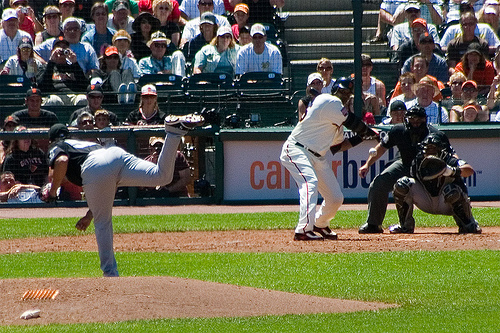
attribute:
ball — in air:
[367, 145, 378, 161]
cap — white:
[238, 20, 293, 44]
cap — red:
[138, 78, 156, 98]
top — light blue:
[203, 39, 248, 81]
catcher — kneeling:
[381, 134, 482, 250]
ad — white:
[221, 136, 498, 201]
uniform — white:
[251, 89, 355, 244]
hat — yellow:
[410, 74, 437, 97]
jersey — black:
[40, 113, 90, 189]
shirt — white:
[269, 87, 356, 171]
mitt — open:
[404, 156, 456, 194]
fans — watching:
[9, 1, 498, 122]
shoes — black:
[292, 226, 341, 244]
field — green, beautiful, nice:
[356, 244, 499, 320]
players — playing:
[43, 74, 475, 266]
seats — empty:
[141, 83, 293, 127]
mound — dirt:
[0, 276, 380, 324]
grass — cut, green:
[193, 262, 405, 301]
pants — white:
[275, 135, 343, 224]